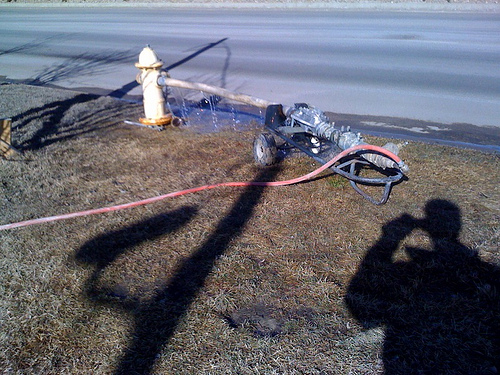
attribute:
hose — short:
[153, 69, 281, 114]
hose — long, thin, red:
[2, 143, 407, 244]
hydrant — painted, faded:
[131, 41, 174, 128]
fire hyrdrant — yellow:
[130, 43, 177, 128]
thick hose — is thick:
[163, 73, 273, 143]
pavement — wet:
[314, 22, 405, 78]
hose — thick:
[169, 79, 261, 109]